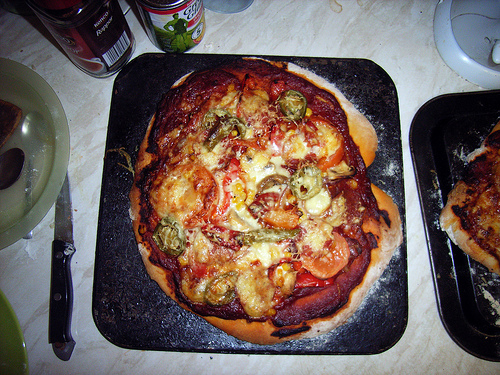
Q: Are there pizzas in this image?
A: Yes, there is a pizza.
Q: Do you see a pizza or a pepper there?
A: Yes, there is a pizza.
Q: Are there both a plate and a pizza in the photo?
A: Yes, there are both a pizza and a plate.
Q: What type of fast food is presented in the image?
A: The fast food is a pizza.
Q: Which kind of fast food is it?
A: The food is a pizza.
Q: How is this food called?
A: This is a pizza.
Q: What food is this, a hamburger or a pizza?
A: This is a pizza.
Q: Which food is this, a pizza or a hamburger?
A: This is a pizza.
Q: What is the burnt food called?
A: The food is a pizza.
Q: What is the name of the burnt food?
A: The food is a pizza.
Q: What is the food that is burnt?
A: The food is a pizza.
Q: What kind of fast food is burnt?
A: The fast food is a pizza.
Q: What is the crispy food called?
A: The food is a pizza.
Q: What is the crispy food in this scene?
A: The food is a pizza.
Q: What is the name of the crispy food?
A: The food is a pizza.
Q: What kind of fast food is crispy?
A: The fast food is a pizza.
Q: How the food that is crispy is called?
A: The food is a pizza.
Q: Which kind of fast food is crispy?
A: The fast food is a pizza.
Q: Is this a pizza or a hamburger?
A: This is a pizza.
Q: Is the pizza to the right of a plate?
A: Yes, the pizza is to the right of a plate.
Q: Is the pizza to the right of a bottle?
A: No, the pizza is to the right of a plate.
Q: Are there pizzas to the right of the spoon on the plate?
A: Yes, there is a pizza to the right of the spoon.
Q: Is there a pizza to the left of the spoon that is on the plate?
A: No, the pizza is to the right of the spoon.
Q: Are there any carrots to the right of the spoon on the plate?
A: No, there is a pizza to the right of the spoon.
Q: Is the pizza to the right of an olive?
A: No, the pizza is to the right of the spoon.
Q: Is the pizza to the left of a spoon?
A: No, the pizza is to the right of a spoon.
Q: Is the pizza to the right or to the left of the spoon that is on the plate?
A: The pizza is to the right of the spoon.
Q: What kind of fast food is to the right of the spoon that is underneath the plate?
A: The food is a pizza.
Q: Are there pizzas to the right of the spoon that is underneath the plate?
A: Yes, there is a pizza to the right of the spoon.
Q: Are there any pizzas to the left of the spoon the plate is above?
A: No, the pizza is to the right of the spoon.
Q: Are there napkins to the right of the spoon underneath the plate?
A: No, there is a pizza to the right of the spoon.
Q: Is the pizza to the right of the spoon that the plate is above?
A: Yes, the pizza is to the right of the spoon.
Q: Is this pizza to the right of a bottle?
A: No, the pizza is to the right of the spoon.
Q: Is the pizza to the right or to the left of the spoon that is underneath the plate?
A: The pizza is to the right of the spoon.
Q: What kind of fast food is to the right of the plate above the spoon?
A: The food is a pizza.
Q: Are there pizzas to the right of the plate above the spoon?
A: Yes, there is a pizza to the right of the plate.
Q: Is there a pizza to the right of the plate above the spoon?
A: Yes, there is a pizza to the right of the plate.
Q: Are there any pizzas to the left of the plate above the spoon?
A: No, the pizza is to the right of the plate.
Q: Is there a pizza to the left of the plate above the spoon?
A: No, the pizza is to the right of the plate.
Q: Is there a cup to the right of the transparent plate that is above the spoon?
A: No, there is a pizza to the right of the plate.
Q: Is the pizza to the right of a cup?
A: No, the pizza is to the right of a plate.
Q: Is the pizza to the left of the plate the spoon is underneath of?
A: No, the pizza is to the right of the plate.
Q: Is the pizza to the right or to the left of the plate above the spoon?
A: The pizza is to the right of the plate.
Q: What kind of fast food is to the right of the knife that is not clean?
A: The food is a pizza.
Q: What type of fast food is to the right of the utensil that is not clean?
A: The food is a pizza.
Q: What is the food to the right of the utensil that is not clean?
A: The food is a pizza.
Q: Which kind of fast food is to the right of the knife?
A: The food is a pizza.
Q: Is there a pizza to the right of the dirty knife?
A: Yes, there is a pizza to the right of the knife.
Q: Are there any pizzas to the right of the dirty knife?
A: Yes, there is a pizza to the right of the knife.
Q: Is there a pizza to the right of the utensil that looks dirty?
A: Yes, there is a pizza to the right of the knife.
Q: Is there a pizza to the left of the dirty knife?
A: No, the pizza is to the right of the knife.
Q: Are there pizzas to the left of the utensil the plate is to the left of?
A: No, the pizza is to the right of the knife.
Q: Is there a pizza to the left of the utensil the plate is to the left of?
A: No, the pizza is to the right of the knife.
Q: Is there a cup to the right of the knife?
A: No, there is a pizza to the right of the knife.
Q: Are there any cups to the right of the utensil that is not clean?
A: No, there is a pizza to the right of the knife.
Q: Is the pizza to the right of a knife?
A: Yes, the pizza is to the right of a knife.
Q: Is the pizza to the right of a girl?
A: No, the pizza is to the right of a knife.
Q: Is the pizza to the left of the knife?
A: No, the pizza is to the right of the knife.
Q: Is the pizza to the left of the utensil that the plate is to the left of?
A: No, the pizza is to the right of the knife.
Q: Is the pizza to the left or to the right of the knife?
A: The pizza is to the right of the knife.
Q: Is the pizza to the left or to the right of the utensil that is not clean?
A: The pizza is to the right of the knife.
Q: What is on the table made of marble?
A: The pizza is on the table.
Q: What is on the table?
A: The pizza is on the table.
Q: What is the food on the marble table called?
A: The food is a pizza.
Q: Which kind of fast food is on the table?
A: The food is a pizza.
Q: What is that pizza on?
A: The pizza is on the table.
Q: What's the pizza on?
A: The pizza is on the table.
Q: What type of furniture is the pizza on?
A: The pizza is on the table.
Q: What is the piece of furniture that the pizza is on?
A: The piece of furniture is a table.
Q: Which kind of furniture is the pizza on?
A: The pizza is on the table.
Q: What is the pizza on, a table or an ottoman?
A: The pizza is on a table.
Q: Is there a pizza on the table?
A: Yes, there is a pizza on the table.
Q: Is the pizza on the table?
A: Yes, the pizza is on the table.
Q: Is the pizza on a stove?
A: No, the pizza is on the table.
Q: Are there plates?
A: Yes, there is a plate.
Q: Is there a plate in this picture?
A: Yes, there is a plate.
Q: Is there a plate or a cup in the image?
A: Yes, there is a plate.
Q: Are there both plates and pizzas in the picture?
A: Yes, there are both a plate and a pizza.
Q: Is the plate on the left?
A: Yes, the plate is on the left of the image.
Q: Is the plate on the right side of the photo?
A: No, the plate is on the left of the image.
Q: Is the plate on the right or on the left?
A: The plate is on the left of the image.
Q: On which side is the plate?
A: The plate is on the left of the image.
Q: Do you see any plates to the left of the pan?
A: Yes, there is a plate to the left of the pan.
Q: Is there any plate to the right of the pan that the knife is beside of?
A: No, the plate is to the left of the pan.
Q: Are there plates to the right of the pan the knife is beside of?
A: No, the plate is to the left of the pan.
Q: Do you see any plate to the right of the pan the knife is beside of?
A: No, the plate is to the left of the pan.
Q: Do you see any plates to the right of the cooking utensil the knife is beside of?
A: No, the plate is to the left of the pan.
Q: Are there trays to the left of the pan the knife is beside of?
A: No, there is a plate to the left of the pan.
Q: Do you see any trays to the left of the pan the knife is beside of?
A: No, there is a plate to the left of the pan.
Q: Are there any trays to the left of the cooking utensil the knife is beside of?
A: No, there is a plate to the left of the pan.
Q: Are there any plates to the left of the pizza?
A: Yes, there is a plate to the left of the pizza.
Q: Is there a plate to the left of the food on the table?
A: Yes, there is a plate to the left of the pizza.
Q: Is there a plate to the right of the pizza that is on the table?
A: No, the plate is to the left of the pizza.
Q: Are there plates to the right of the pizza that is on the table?
A: No, the plate is to the left of the pizza.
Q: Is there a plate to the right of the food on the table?
A: No, the plate is to the left of the pizza.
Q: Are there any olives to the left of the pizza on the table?
A: No, there is a plate to the left of the pizza.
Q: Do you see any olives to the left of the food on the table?
A: No, there is a plate to the left of the pizza.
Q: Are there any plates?
A: Yes, there is a plate.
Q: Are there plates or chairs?
A: Yes, there is a plate.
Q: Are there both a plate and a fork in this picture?
A: No, there is a plate but no forks.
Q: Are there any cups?
A: No, there are no cups.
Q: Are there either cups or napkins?
A: No, there are no cups or napkins.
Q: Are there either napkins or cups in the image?
A: No, there are no cups or napkins.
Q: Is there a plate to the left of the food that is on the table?
A: Yes, there is a plate to the left of the pizza.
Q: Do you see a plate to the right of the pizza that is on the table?
A: No, the plate is to the left of the pizza.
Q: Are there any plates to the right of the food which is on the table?
A: No, the plate is to the left of the pizza.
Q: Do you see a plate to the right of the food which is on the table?
A: No, the plate is to the left of the pizza.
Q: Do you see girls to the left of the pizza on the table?
A: No, there is a plate to the left of the pizza.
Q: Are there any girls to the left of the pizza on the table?
A: No, there is a plate to the left of the pizza.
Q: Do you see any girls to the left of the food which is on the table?
A: No, there is a plate to the left of the pizza.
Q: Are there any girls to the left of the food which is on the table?
A: No, there is a plate to the left of the pizza.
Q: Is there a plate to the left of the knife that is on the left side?
A: Yes, there is a plate to the left of the knife.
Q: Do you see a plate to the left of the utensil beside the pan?
A: Yes, there is a plate to the left of the knife.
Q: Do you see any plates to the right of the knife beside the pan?
A: No, the plate is to the left of the knife.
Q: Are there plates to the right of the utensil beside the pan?
A: No, the plate is to the left of the knife.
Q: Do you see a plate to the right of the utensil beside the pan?
A: No, the plate is to the left of the knife.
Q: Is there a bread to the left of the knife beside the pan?
A: No, there is a plate to the left of the knife.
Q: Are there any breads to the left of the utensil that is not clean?
A: No, there is a plate to the left of the knife.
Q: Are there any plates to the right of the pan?
A: No, the plate is to the left of the pan.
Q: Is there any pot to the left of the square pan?
A: No, there is a plate to the left of the pan.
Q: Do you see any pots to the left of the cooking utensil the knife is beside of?
A: No, there is a plate to the left of the pan.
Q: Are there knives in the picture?
A: Yes, there is a knife.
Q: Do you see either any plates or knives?
A: Yes, there is a knife.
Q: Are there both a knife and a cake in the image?
A: No, there is a knife but no cakes.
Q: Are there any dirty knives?
A: Yes, there is a dirty knife.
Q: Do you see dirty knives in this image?
A: Yes, there is a dirty knife.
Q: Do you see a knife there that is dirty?
A: Yes, there is a knife that is dirty.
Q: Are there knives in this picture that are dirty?
A: Yes, there is a knife that is dirty.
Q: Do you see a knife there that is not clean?
A: Yes, there is a dirty knife.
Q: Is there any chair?
A: No, there are no chairs.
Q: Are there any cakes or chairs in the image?
A: No, there are no chairs or cakes.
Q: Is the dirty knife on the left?
A: Yes, the knife is on the left of the image.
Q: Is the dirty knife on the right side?
A: No, the knife is on the left of the image.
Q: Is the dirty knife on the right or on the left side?
A: The knife is on the left of the image.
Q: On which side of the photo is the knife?
A: The knife is on the left of the image.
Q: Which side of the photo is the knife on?
A: The knife is on the left of the image.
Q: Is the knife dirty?
A: Yes, the knife is dirty.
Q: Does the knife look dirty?
A: Yes, the knife is dirty.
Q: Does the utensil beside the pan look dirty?
A: Yes, the knife is dirty.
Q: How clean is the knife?
A: The knife is dirty.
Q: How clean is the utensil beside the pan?
A: The knife is dirty.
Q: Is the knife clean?
A: No, the knife is dirty.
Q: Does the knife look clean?
A: No, the knife is dirty.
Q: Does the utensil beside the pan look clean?
A: No, the knife is dirty.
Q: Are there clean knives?
A: No, there is a knife but it is dirty.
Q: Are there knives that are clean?
A: No, there is a knife but it is dirty.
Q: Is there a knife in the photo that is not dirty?
A: No, there is a knife but it is dirty.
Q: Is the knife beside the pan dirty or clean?
A: The knife is dirty.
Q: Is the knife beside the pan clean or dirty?
A: The knife is dirty.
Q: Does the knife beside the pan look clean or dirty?
A: The knife is dirty.